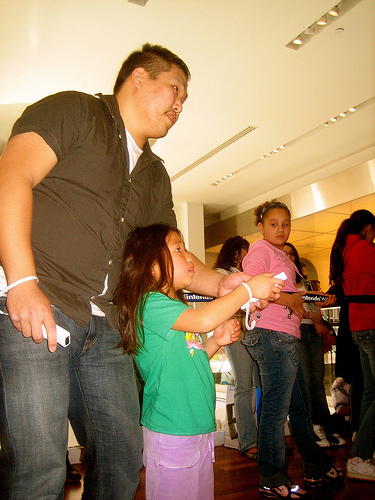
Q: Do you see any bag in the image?
A: No, there are no bags.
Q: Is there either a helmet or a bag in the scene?
A: No, there are no bags or helmets.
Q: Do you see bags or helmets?
A: No, there are no bags or helmets.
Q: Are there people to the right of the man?
A: Yes, there is a person to the right of the man.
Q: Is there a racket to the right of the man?
A: No, there is a person to the right of the man.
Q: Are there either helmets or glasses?
A: No, there are no glasses or helmets.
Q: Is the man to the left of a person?
A: Yes, the man is to the left of a person.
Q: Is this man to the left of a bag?
A: No, the man is to the left of a person.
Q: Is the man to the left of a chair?
A: No, the man is to the left of a person.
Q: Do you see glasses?
A: No, there are no glasses.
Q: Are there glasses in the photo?
A: No, there are no glasses.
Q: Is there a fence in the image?
A: No, there are no fences.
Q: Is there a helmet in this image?
A: No, there are no helmets.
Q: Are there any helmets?
A: No, there are no helmets.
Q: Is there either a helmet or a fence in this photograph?
A: No, there are no helmets or fences.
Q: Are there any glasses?
A: No, there are no glasses.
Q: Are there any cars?
A: No, there are no cars.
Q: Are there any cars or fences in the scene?
A: No, there are no cars or fences.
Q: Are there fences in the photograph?
A: No, there are no fences.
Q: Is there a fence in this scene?
A: No, there are no fences.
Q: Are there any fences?
A: No, there are no fences.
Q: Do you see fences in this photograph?
A: No, there are no fences.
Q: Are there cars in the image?
A: No, there are no cars.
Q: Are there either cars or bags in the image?
A: No, there are no cars or bags.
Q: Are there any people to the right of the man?
A: Yes, there is a person to the right of the man.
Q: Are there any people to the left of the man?
A: No, the person is to the right of the man.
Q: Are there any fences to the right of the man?
A: No, there is a person to the right of the man.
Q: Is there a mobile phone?
A: No, there are no cell phones.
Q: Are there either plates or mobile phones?
A: No, there are no mobile phones or plates.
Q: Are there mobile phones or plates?
A: No, there are no mobile phones or plates.